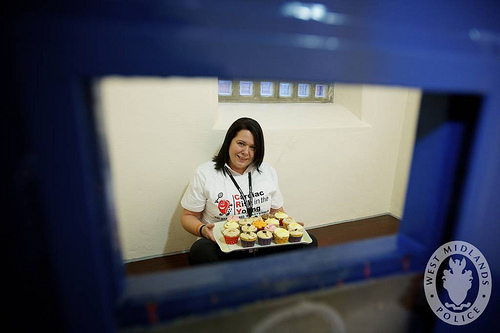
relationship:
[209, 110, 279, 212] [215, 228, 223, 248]
woman holding tray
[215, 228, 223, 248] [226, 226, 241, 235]
tray has cupcake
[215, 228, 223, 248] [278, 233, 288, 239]
tray has cupcake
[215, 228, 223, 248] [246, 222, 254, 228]
tray has cupcake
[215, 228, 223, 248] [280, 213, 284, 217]
tray has cupcake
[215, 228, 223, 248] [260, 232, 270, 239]
tray has cupcake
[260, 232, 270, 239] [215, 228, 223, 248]
cupcake on tray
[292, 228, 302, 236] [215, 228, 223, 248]
cupcake on tray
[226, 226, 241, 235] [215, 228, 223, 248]
cupcake on tray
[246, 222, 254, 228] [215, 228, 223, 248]
cupcake on tray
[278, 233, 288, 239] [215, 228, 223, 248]
cupcake on tray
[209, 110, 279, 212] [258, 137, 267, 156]
woman has hair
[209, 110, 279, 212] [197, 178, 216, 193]
woman wearing t-shirt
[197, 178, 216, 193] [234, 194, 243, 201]
t-shirt has letter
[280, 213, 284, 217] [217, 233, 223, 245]
cupcake of t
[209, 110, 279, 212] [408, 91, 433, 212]
woman in window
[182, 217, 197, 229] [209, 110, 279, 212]
arm of woman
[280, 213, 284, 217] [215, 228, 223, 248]
cupcake on tray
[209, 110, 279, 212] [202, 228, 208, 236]
woman has wrist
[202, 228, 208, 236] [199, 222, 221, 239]
wrist has band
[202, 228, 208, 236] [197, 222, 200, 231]
wrist has band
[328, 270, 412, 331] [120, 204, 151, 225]
door has glass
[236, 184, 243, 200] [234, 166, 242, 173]
lanyard around neck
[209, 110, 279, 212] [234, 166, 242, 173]
woman has neck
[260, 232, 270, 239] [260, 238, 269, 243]
cupcake has liner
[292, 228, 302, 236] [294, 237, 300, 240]
cupcake has liner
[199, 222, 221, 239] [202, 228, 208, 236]
band on wrist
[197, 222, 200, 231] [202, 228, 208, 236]
band on wrist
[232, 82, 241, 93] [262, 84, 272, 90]
bar on window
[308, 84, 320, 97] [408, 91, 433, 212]
bar on window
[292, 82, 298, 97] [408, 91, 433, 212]
bar on window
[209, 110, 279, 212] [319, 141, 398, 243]
woman in jail cell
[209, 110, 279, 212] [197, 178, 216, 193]
woman in t-shirt